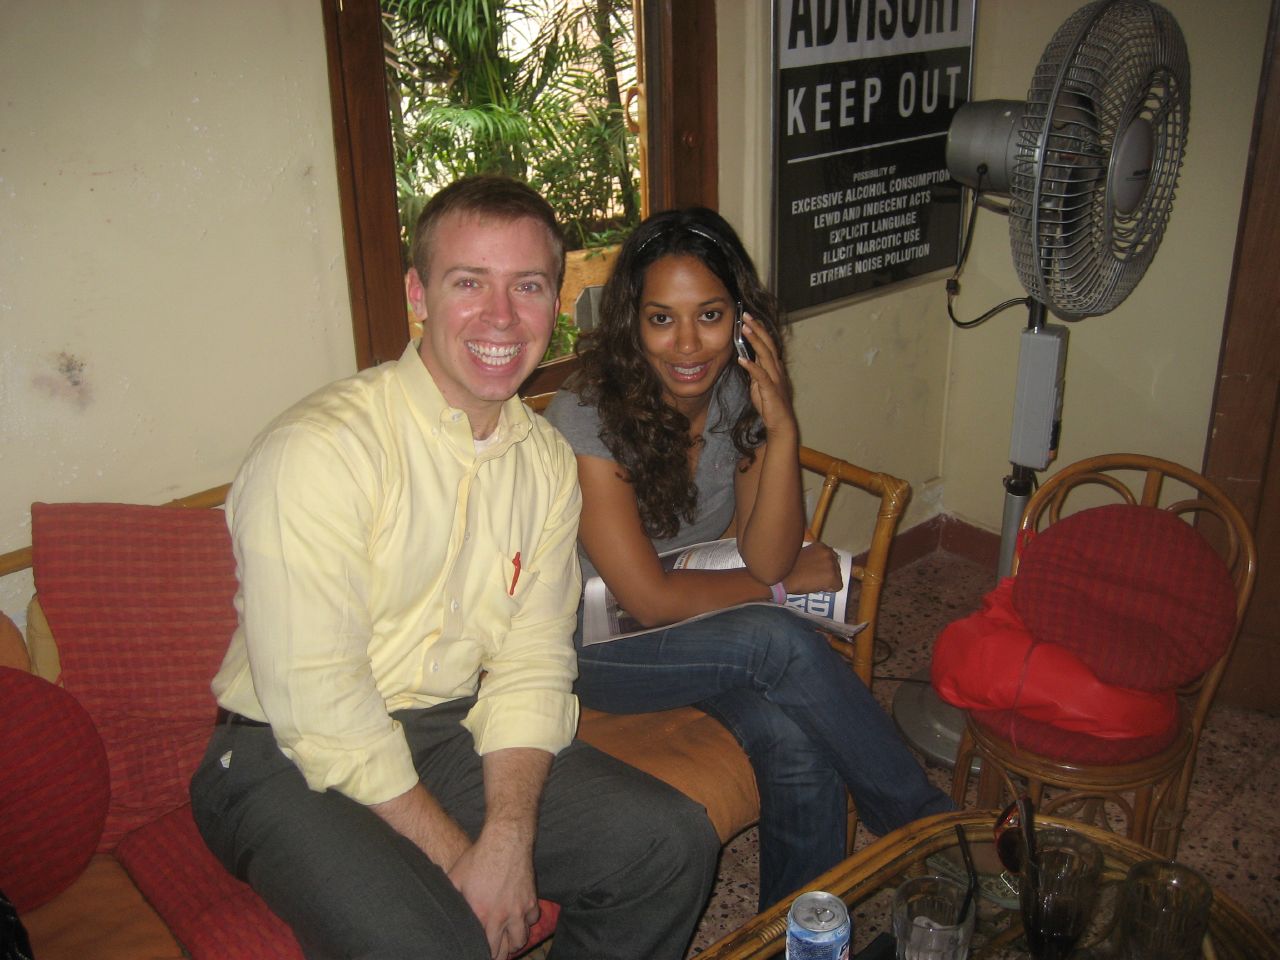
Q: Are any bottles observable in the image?
A: No, there are no bottles.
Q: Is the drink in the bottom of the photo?
A: Yes, the drink is in the bottom of the image.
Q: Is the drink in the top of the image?
A: No, the drink is in the bottom of the image.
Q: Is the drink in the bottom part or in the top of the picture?
A: The drink is in the bottom of the image.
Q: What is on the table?
A: The drink is on the table.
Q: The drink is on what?
A: The drink is on the table.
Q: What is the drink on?
A: The drink is on the table.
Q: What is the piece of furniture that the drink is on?
A: The piece of furniture is a table.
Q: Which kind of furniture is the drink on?
A: The drink is on the table.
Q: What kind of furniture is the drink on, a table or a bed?
A: The drink is on a table.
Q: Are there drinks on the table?
A: Yes, there is a drink on the table.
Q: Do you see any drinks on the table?
A: Yes, there is a drink on the table.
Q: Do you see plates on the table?
A: No, there is a drink on the table.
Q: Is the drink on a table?
A: Yes, the drink is on a table.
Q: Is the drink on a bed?
A: No, the drink is on a table.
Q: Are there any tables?
A: Yes, there is a table.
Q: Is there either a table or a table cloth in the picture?
A: Yes, there is a table.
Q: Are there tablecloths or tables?
A: Yes, there is a table.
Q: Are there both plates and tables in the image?
A: No, there is a table but no plates.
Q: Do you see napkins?
A: No, there are no napkins.